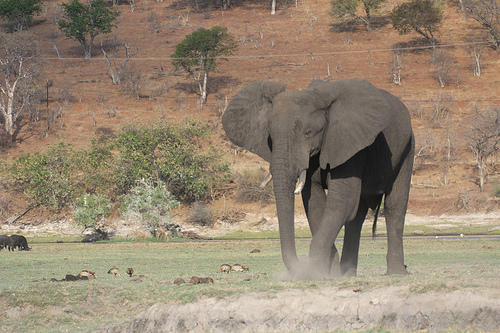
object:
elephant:
[220, 77, 417, 278]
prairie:
[0, 208, 500, 329]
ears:
[221, 80, 289, 164]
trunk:
[268, 123, 300, 275]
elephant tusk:
[293, 168, 307, 194]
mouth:
[260, 140, 324, 179]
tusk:
[259, 174, 274, 187]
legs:
[307, 155, 362, 279]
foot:
[307, 262, 334, 280]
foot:
[339, 266, 360, 278]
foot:
[383, 265, 416, 276]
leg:
[339, 199, 371, 277]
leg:
[383, 178, 412, 275]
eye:
[304, 130, 313, 138]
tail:
[371, 195, 383, 241]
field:
[1, 0, 497, 330]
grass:
[214, 0, 288, 46]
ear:
[221, 79, 290, 163]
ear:
[318, 77, 392, 171]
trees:
[171, 26, 243, 110]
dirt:
[1, 231, 500, 331]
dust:
[223, 249, 414, 321]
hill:
[0, 0, 223, 227]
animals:
[124, 267, 136, 278]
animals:
[64, 275, 82, 281]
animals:
[5, 234, 34, 252]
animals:
[0, 234, 10, 251]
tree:
[0, 120, 261, 259]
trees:
[463, 92, 500, 194]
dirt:
[0, 31, 495, 220]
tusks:
[259, 173, 273, 188]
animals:
[219, 263, 233, 274]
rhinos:
[0, 234, 17, 254]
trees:
[53, 0, 122, 83]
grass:
[210, 221, 496, 295]